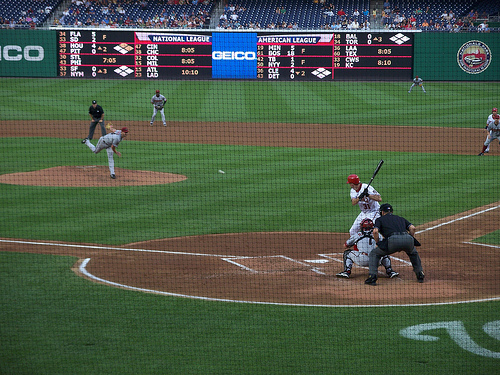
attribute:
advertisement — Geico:
[208, 27, 260, 81]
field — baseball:
[4, 74, 493, 367]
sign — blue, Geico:
[216, 48, 257, 68]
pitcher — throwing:
[79, 117, 136, 182]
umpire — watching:
[86, 99, 105, 144]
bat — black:
[353, 158, 386, 195]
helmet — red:
[345, 176, 362, 185]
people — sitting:
[4, 4, 494, 33]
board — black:
[60, 27, 411, 83]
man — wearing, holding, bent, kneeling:
[84, 86, 112, 160]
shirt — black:
[92, 107, 105, 121]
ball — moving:
[215, 168, 224, 178]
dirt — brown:
[9, 118, 495, 303]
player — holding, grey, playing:
[342, 176, 381, 233]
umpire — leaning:
[369, 199, 424, 294]